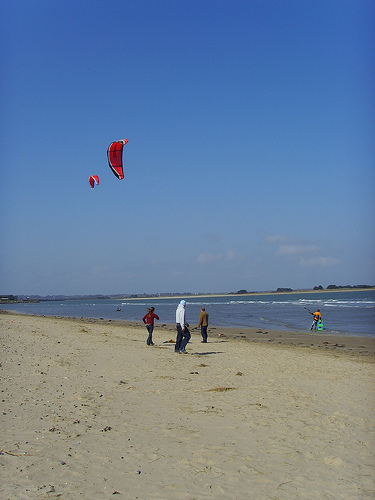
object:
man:
[175, 299, 191, 354]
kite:
[164, 339, 177, 343]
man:
[309, 308, 322, 331]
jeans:
[201, 326, 208, 341]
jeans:
[177, 325, 191, 350]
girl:
[142, 307, 160, 347]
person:
[176, 300, 191, 355]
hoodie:
[175, 304, 186, 329]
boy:
[142, 307, 160, 346]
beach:
[0, 312, 374, 497]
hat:
[180, 299, 187, 305]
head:
[150, 306, 155, 312]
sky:
[0, 0, 373, 287]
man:
[197, 307, 209, 343]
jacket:
[197, 311, 209, 327]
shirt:
[142, 313, 160, 326]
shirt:
[314, 311, 322, 321]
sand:
[0, 309, 375, 499]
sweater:
[197, 312, 209, 328]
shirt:
[176, 304, 186, 330]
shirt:
[197, 311, 209, 328]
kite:
[107, 138, 129, 181]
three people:
[142, 299, 209, 355]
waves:
[119, 296, 373, 309]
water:
[0, 296, 374, 329]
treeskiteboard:
[317, 319, 323, 331]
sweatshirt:
[176, 300, 186, 329]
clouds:
[267, 231, 338, 270]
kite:
[88, 175, 99, 191]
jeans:
[146, 325, 154, 345]